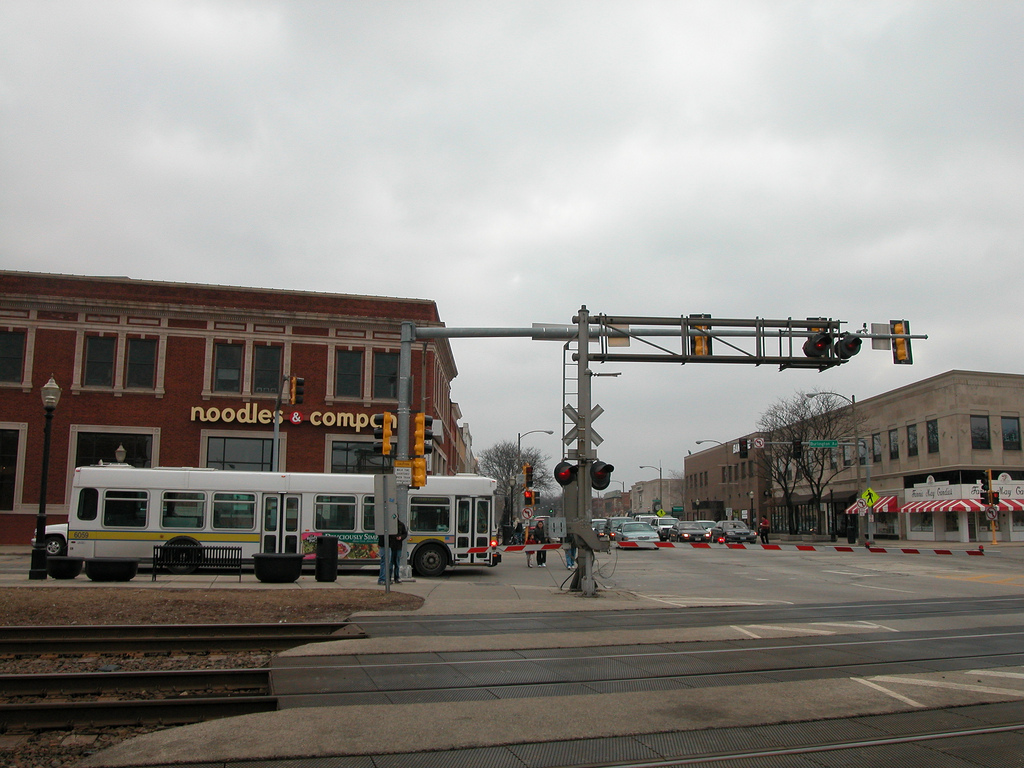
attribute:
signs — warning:
[586, 274, 973, 426]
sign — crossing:
[551, 408, 653, 475]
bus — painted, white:
[24, 423, 549, 601]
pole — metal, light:
[553, 356, 625, 648]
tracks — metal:
[48, 589, 241, 721]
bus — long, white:
[64, 461, 499, 576]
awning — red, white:
[846, 487, 1022, 513]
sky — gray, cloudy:
[3, 3, 1023, 492]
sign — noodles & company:
[187, 395, 382, 430]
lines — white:
[854, 669, 1023, 709]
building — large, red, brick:
[14, 258, 453, 576]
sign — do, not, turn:
[508, 498, 535, 531]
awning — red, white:
[843, 480, 993, 519]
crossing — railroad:
[605, 538, 994, 578]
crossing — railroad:
[616, 536, 993, 593]